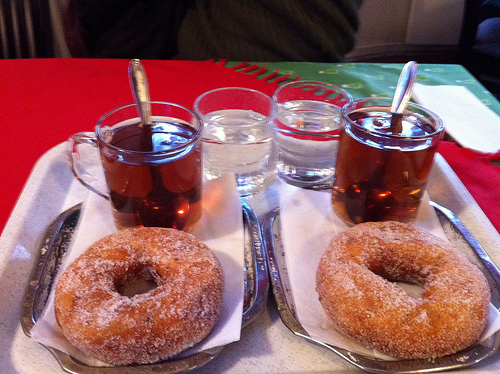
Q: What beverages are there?
A: Tea.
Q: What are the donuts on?
A: Trays.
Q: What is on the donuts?
A: Sugar.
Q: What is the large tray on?
A: Table.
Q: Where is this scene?
A: Restaurant.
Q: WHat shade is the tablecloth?
A: Red.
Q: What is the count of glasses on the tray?
A: 4.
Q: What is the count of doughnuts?
A: 2.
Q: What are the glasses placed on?
A: A tray.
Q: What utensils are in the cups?
A: Spoons.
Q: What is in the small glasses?
A: Water.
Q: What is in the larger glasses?
A: Tea.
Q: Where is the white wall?
A: The wall is in the background.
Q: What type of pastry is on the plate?
A: A donut.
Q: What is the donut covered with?
A: Sugar.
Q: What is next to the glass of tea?
A: A donut.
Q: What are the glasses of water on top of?
A: A plastic tray.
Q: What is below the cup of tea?
A: A white napkin.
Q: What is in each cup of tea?
A: A silver spoon.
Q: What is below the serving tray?
A: A large plastic tray.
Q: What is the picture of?
A: A food tray on a dining table.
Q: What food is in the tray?
A: Two donuts and two cups of tea.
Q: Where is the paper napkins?
A: Under the donuts and tea cups on the trays.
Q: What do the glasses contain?
A: Water.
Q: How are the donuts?
A: Brown and coated with ground sugar.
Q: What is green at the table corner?
A: Table cover.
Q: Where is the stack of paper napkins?
A: At the corner of the table on the green table cloth.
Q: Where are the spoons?
A: Inside the teacups.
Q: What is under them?
A: Napkins.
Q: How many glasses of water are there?
A: Two.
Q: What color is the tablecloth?
A: Red.